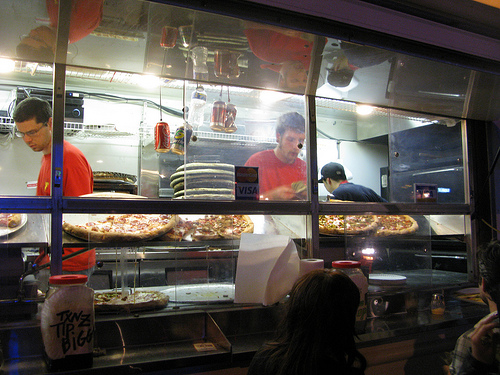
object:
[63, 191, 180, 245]
whole pizza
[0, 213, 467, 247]
shelf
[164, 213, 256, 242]
whole pizza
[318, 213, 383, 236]
whole pizza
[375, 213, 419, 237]
whole pizza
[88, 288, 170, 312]
whole pizza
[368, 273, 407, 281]
plates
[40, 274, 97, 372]
tip jar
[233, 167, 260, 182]
credit card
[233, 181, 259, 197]
credit card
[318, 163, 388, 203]
chef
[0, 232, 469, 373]
counter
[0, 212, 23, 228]
pizza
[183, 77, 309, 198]
window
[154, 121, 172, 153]
soda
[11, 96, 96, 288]
man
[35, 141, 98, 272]
shirt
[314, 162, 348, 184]
baseball hat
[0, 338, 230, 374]
ledge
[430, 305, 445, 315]
parmesan cheese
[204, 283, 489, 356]
ledge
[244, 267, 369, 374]
person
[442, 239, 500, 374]
person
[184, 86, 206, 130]
water bottle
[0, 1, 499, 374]
food truck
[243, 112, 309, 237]
worker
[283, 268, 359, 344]
head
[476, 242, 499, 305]
head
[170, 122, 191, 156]
soda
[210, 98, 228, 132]
soda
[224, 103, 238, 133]
soda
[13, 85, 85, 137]
radio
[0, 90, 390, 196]
wall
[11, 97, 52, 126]
hair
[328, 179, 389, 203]
shirt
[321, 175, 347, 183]
hair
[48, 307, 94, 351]
writing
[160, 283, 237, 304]
plate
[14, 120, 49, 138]
glasses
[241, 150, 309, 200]
shirt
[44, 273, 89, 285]
lid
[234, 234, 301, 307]
paper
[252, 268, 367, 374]
hair